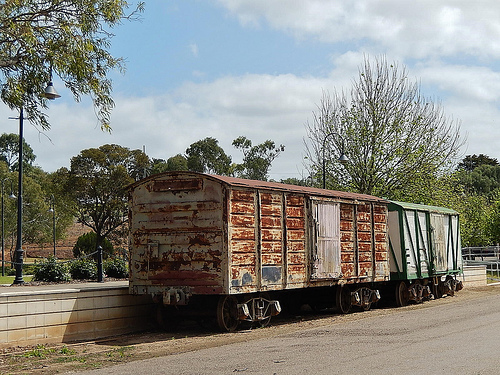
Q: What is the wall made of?
A: Bricks.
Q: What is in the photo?
A: Train cars.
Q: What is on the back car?
A: Rust.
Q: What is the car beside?
A: Barrier.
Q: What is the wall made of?
A: Brick.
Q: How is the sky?
A: Blue.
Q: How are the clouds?
A: Fluffy.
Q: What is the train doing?
A: Parked.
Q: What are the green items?
A: Trees.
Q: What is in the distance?
A: Vegetation.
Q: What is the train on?
A: Wheels.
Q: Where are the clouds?
A: In the sky.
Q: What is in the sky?
A: Clouds.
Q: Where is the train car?
A: On the tracks.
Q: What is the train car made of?
A: Metal.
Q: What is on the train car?
A: Rust.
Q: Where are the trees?
A: Behind the small wall.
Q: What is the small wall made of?
A: White bricks.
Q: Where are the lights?
A: On the lamp posts.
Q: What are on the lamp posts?
A: Lights.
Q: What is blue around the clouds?
A: The sky.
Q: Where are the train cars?
A: Side of road.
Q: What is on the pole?
A: A light.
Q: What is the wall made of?
A: Brick.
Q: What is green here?
A: Trees.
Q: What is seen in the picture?
A: Old train box.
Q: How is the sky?
A: With some clouds.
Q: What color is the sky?
A: Blue.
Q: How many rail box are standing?
A: 2.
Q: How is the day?
A: Sunny.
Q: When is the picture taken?
A: Daytime.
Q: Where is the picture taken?
A: At a train station.